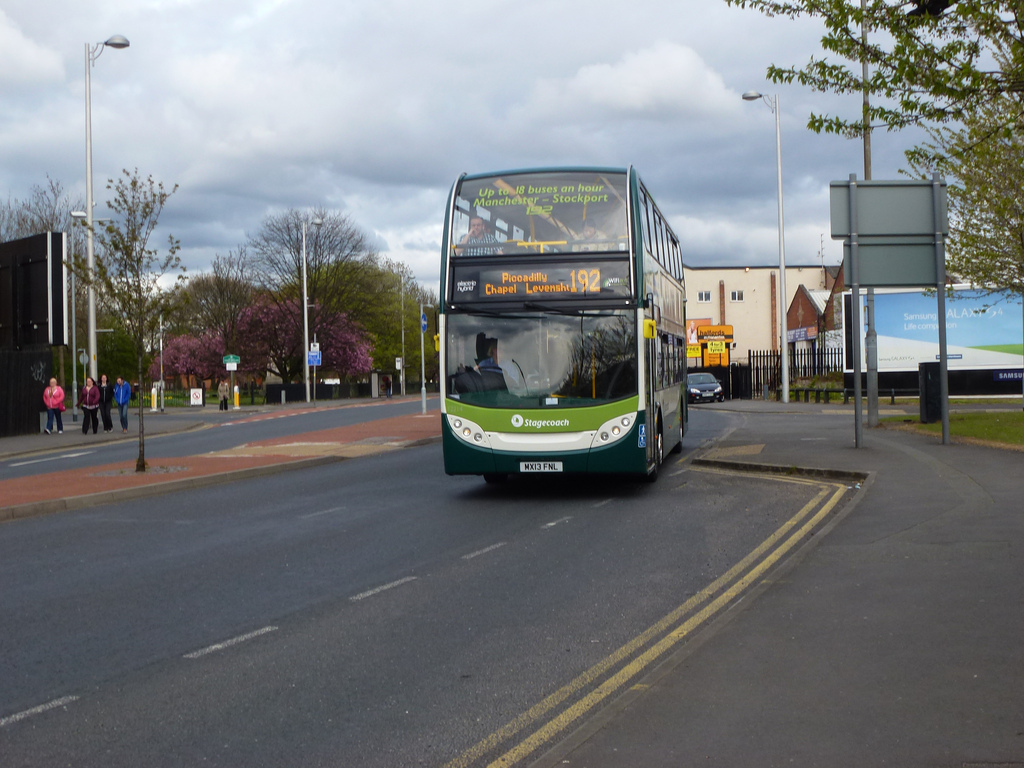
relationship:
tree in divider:
[87, 208, 194, 459] [42, 456, 228, 498]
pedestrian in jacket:
[115, 359, 157, 437] [105, 368, 138, 412]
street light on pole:
[80, 32, 132, 380] [82, 39, 98, 362]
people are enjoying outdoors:
[37, 348, 182, 450] [11, 26, 994, 739]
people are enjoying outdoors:
[43, 377, 67, 435] [11, 26, 994, 739]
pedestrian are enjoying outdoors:
[115, 379, 131, 432] [11, 26, 994, 739]